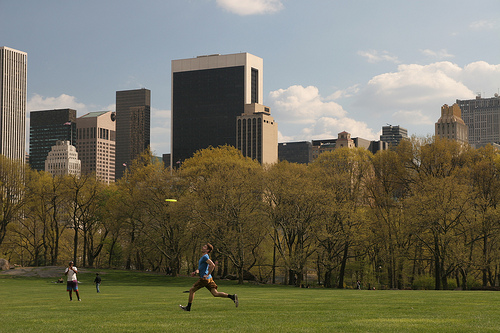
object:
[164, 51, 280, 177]
building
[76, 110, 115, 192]
building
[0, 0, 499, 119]
cloud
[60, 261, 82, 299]
man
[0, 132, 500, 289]
trees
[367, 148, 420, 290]
trees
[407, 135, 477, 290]
tree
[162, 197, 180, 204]
frisbee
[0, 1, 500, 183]
cityscape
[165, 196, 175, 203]
disc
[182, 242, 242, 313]
man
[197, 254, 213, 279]
shirt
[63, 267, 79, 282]
shirt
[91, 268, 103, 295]
people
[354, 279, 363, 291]
people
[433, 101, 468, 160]
building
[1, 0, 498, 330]
city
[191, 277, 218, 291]
shorts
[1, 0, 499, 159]
sky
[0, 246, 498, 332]
field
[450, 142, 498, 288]
tree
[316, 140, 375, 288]
tree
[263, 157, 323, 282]
tree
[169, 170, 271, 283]
tree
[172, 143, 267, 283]
tree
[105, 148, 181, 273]
tree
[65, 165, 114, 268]
tree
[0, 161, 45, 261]
tree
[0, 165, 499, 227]
tree level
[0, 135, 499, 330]
city park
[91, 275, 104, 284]
jacket